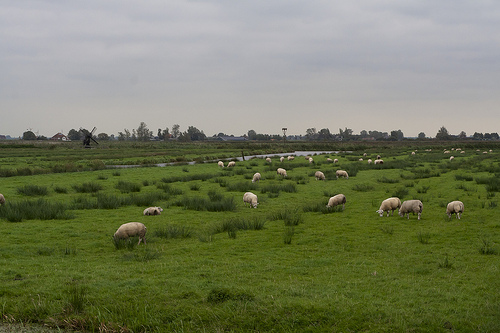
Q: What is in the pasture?
A: Sheeps.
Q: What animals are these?
A: Sheep.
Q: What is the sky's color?
A: Gray.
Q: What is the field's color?
A: Green.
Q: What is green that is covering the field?
A: Grass.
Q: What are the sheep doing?
A: Grazing.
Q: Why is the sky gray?
A: Cloudy.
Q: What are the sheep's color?
A: White.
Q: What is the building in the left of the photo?
A: Windmill.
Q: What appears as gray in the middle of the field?
A: Water.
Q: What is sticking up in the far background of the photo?
A: Trees.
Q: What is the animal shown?
A: Sheep.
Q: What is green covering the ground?
A: Grass.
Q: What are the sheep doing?
A: Grazing.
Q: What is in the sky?
A: Clouds.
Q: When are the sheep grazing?
A: Cloudy day.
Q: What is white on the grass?
A: Sheep.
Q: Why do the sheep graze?
A: Hungry.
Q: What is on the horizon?
A: Trees.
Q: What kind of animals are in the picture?
A: Sheep.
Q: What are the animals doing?
A: Eating.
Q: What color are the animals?
A: White.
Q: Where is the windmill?
A: Back left.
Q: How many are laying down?
A: One.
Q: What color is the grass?
A: Green.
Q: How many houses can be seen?
A: One.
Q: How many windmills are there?
A: One.